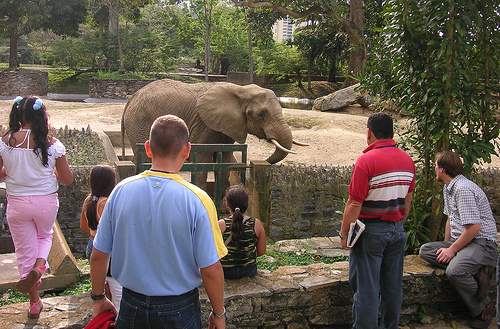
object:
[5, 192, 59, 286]
pants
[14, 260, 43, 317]
foot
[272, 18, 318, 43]
building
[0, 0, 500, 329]
zoo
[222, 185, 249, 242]
hair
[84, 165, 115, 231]
hair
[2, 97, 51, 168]
hair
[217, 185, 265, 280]
child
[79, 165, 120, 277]
child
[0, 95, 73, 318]
child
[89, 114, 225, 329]
child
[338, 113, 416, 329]
man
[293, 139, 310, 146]
tusks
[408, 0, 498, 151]
tree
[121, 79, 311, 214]
elephant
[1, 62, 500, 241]
enclosure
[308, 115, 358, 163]
ground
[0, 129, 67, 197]
blouse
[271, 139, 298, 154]
tusk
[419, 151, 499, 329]
gentleman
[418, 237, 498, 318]
ensemble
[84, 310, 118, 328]
backpack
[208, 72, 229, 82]
ground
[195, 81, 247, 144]
ear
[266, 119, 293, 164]
trunk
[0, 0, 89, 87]
trees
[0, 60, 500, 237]
habitat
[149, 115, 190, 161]
buzz cut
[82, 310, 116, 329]
straps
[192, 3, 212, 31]
branch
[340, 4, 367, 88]
branch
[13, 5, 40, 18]
branch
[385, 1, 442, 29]
branch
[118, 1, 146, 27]
branch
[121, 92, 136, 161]
tail